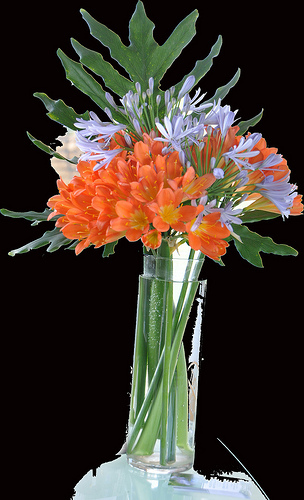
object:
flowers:
[147, 186, 198, 231]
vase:
[128, 257, 201, 471]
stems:
[160, 257, 170, 465]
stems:
[123, 252, 206, 454]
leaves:
[188, 204, 228, 259]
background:
[2, 1, 304, 500]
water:
[124, 271, 206, 475]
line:
[135, 269, 207, 288]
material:
[63, 431, 272, 500]